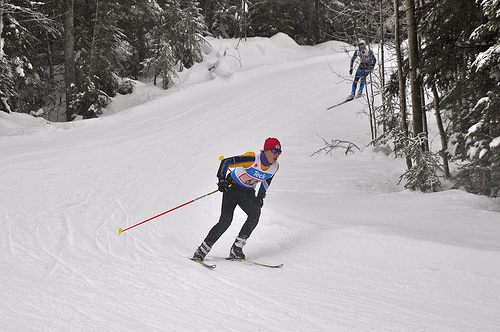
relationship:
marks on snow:
[82, 236, 161, 270] [62, 129, 202, 191]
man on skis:
[192, 137, 283, 260] [193, 256, 285, 273]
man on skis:
[192, 137, 283, 260] [192, 249, 287, 272]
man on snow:
[192, 137, 283, 260] [2, 31, 497, 328]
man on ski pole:
[192, 137, 283, 260] [353, 55, 361, 70]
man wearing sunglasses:
[192, 137, 283, 260] [260, 141, 290, 161]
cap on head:
[255, 130, 291, 157] [249, 127, 291, 172]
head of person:
[249, 127, 291, 172] [187, 112, 297, 281]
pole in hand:
[118, 188, 217, 234] [214, 179, 228, 190]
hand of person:
[214, 179, 228, 190] [192, 136, 282, 270]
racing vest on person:
[228, 150, 278, 197] [192, 136, 282, 270]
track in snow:
[89, 240, 138, 272] [104, 240, 262, 322]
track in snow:
[93, 257, 158, 292] [330, 217, 465, 259]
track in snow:
[89, 240, 138, 272] [8, 130, 180, 330]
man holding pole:
[192, 137, 283, 260] [120, 188, 218, 232]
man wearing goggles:
[192, 137, 283, 260] [260, 150, 279, 159]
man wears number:
[192, 137, 283, 260] [235, 173, 259, 190]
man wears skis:
[191, 138, 283, 271] [182, 242, 214, 273]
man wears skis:
[191, 138, 283, 271] [202, 247, 305, 279]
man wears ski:
[192, 137, 283, 260] [189, 252, 217, 267]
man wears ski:
[192, 137, 283, 260] [222, 250, 286, 269]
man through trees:
[342, 40, 376, 102] [362, 2, 393, 150]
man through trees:
[342, 40, 376, 102] [388, 0, 430, 191]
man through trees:
[342, 40, 376, 102] [412, 2, 467, 194]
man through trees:
[342, 40, 376, 102] [453, 0, 499, 203]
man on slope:
[192, 137, 283, 260] [36, 194, 339, 300]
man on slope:
[342, 40, 376, 102] [261, 50, 372, 137]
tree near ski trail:
[19, 10, 145, 120] [337, 206, 470, 327]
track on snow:
[402, 260, 450, 279] [2, 31, 497, 328]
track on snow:
[89, 240, 138, 272] [2, 31, 497, 328]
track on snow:
[187, 100, 263, 118] [2, 31, 497, 328]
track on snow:
[89, 240, 138, 272] [47, 278, 114, 316]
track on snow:
[106, 194, 184, 268] [49, 125, 384, 310]